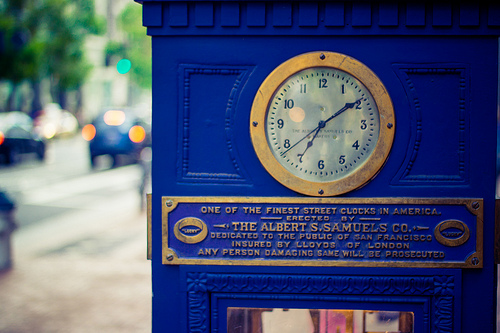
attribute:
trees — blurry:
[3, 4, 150, 104]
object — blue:
[148, 4, 495, 331]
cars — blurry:
[3, 103, 159, 270]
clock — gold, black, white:
[242, 36, 413, 216]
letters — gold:
[163, 200, 489, 277]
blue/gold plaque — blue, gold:
[155, 191, 490, 275]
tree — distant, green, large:
[3, 0, 88, 101]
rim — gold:
[248, 49, 395, 199]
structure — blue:
[123, 1, 499, 331]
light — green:
[113, 56, 129, 76]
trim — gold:
[247, 45, 400, 196]